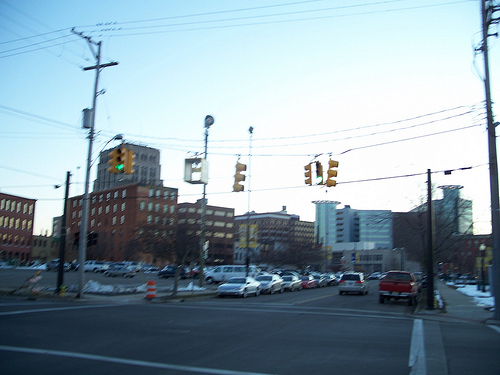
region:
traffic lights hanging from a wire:
[56, 105, 386, 211]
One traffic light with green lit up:
[101, 141, 153, 186]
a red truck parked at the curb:
[363, 254, 429, 332]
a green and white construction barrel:
[138, 273, 171, 307]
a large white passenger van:
[206, 260, 257, 287]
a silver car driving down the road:
[328, 271, 366, 306]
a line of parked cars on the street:
[216, 271, 356, 298]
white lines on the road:
[40, 285, 465, 373]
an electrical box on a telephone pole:
[70, 99, 97, 139]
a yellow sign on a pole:
[235, 213, 267, 250]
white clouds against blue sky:
[11, 13, 52, 77]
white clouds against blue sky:
[9, 66, 36, 98]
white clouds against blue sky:
[0, 103, 45, 155]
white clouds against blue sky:
[138, 21, 190, 69]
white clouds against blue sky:
[205, 19, 295, 87]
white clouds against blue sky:
[345, 46, 399, 114]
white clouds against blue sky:
[286, 79, 373, 134]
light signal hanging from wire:
[181, 148, 208, 196]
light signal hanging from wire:
[221, 153, 255, 194]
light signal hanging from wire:
[296, 149, 334, 200]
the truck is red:
[366, 261, 438, 316]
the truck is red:
[373, 220, 416, 306]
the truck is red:
[358, 250, 462, 329]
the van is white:
[195, 254, 262, 304]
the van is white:
[168, 258, 285, 291]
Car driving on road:
[329, 254, 373, 331]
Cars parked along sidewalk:
[191, 268, 336, 304]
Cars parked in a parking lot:
[33, 244, 227, 299]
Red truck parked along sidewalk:
[377, 261, 430, 323]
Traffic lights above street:
[93, 117, 358, 203]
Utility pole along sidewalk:
[70, 77, 134, 315]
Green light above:
[101, 146, 166, 203]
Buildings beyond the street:
[36, 164, 471, 286]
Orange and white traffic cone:
[131, 267, 170, 313]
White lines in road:
[194, 298, 427, 336]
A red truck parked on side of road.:
[363, 258, 425, 310]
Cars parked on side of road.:
[216, 263, 327, 292]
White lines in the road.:
[206, 298, 381, 324]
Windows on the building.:
[91, 196, 181, 221]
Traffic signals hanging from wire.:
[298, 139, 348, 186]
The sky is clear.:
[147, 41, 377, 125]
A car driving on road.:
[316, 258, 372, 308]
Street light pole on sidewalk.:
[178, 112, 225, 292]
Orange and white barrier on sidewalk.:
[136, 278, 163, 304]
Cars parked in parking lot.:
[104, 255, 222, 282]